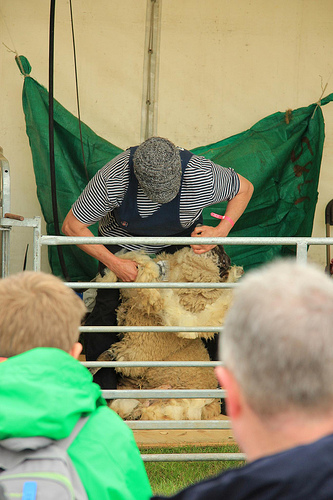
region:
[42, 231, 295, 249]
metal bar on fence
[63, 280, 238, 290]
metal bar on fence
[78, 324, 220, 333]
metal bar on fence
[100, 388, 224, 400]
metal bar on fence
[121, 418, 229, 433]
metal bar on fence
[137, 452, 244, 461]
metal bar on fence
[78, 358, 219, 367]
metal bar on fence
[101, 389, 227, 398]
metal bar on fence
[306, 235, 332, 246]
metal bar on fence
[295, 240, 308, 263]
metal bar on fence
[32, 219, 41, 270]
metal bar on fence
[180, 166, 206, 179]
blue stripe on white shirt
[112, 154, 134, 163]
blue stripe on white shirt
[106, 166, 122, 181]
blue stripe on white shirt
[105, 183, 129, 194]
blue stripe on white shirt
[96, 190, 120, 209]
blue stripe on white shirt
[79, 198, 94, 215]
blue stripe on white shirt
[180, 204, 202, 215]
blue stripe on white shirt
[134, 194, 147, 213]
blue stripe on white shirt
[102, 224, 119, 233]
blue stripe on white shirt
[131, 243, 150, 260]
blue stripe on white shirt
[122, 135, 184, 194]
small gray wool cap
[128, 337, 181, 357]
coarse brown wool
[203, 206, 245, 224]
pink and white wrist band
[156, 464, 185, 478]
green grass on the ground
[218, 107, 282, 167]
green fabric on the wall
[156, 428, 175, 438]
small stone on the ground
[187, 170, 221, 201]
blue and white stripe shirt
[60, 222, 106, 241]
muscles in man's hand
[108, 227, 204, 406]
tall silver iron railing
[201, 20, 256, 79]
small black spots on the wall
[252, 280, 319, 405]
the hair is gray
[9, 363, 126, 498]
the sweatshirt is green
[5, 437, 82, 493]
the backpack is gray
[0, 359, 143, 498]
backpack on the back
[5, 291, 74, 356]
the hair is brown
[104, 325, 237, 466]
the gate is metal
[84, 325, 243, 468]
the gate is silver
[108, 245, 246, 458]
the animal behind gate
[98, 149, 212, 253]
the shirt is striped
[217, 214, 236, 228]
the band is pink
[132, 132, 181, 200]
a gray hat on a head.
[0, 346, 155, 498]
A green jacket with a hood.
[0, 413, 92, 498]
A gray back pack on a back.